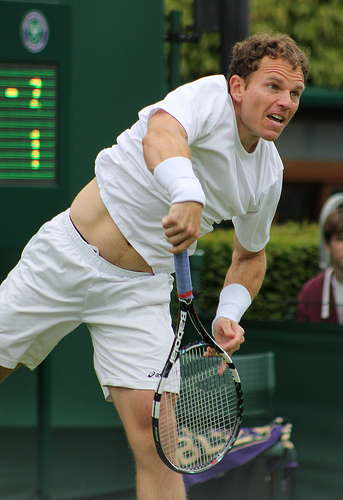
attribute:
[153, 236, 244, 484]
racquet — name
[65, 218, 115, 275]
band — elastic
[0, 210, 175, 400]
shorts — white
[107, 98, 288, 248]
shirt —  SHORT 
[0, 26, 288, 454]
man —  HOLDING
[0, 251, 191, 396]
shorts — PANTS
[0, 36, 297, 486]
man — WEARING,  CLOTHING ,  WEARING,  forhead, wrinkles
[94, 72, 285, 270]
shirt —  WHITE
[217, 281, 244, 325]
band —  ARM, WHITE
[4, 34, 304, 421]
man —  playing, WEARING, SLEEVED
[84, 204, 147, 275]
belly — BUTTON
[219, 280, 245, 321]
band —  ARM 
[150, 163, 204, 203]
band —  ARM 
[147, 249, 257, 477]
racket — tennis, blue 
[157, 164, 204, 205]
wrist — man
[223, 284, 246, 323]
wrist — man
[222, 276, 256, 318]
sweatbands — white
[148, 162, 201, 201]
sweatbands — white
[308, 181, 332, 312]
person —  watching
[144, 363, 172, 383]
logo — Asics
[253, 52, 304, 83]
forhead — wrinkles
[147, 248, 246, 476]
racket — tennis,  blue, black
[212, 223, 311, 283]
hedges — green, row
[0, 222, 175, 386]
shorts — white,   WHITE, tennis, black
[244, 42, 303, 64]
hair — curly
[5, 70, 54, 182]
scoreboard — behind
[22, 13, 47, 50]
logo —  over 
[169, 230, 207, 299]
handle — blue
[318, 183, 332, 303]
person — watching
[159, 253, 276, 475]
racket — white, black, tennis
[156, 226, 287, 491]
racket — tennis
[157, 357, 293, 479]
strings — white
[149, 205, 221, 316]
handle — purple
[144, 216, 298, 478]
racket — tennis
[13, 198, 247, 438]
shorts — white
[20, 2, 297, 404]
player — tennis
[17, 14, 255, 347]
player — tennis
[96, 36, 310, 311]
shirt — white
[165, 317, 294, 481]
chair — green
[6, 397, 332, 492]
court — tennis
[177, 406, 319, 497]
towel — purple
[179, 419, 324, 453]
lettering — gold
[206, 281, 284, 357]
wristbands — white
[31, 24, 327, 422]
player — tennis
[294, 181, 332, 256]
man — watching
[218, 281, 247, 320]
wrist band — white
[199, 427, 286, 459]
towel — purple